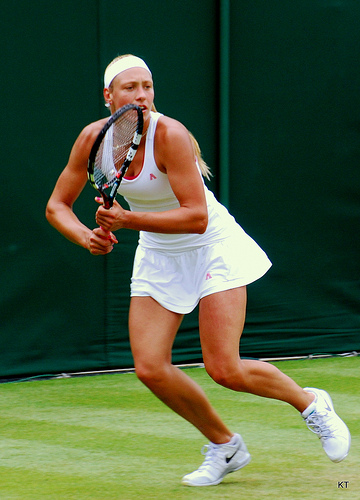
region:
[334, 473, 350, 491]
photo tag on the picture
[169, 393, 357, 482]
white tennis shoes with the nike swoosh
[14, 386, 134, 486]
green grass on the tennis court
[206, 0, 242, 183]
pole at the back of the court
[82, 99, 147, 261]
tennis racket in the girl's hand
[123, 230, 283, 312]
white tennis skirt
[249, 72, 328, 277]
green tarp wall behind the court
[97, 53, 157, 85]
white sweat band on the girl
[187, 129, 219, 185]
blonde hair down her back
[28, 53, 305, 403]
girl playing tennis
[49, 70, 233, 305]
woman holding a tennis racket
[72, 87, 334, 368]
woman wearing a tennis uniform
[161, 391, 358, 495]
woman wearing tennis shoes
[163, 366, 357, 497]
woman wearing nike sneakers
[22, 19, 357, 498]
woman standing on tennis court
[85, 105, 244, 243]
woman wearing a white tank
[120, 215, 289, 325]
woman wearing a white skirt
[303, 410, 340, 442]
shoelaces on white shoe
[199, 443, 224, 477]
shoelaces on white shoe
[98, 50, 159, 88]
woman wearing a headband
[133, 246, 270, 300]
short white tennis skirt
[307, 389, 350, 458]
white tennis shoes with dark check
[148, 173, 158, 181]
hot pink symbol on shirt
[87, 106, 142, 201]
black and white tennis racket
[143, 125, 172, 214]
white tank top with emblem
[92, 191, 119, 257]
hands holding tennis racket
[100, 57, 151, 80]
solid white head band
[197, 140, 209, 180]
strands of long blonde hair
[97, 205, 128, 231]
hand gripping handle of racket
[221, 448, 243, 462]
dark emblem on white shoe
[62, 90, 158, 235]
a black tennis racket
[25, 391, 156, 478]
a green tennis court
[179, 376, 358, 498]
white and black nike sneakers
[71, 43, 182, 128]
a woman wearing a white headband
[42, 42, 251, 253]
a woman playing tennis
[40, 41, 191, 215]
a woman holding a tennis racket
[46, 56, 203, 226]
a woman wearing a tank top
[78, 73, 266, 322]
a woman wearing a white skirt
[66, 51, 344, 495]
a woman wearing nike sneakers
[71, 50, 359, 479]
a woman wearing white nike sneakers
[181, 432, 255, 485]
Foot of tennis player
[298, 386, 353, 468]
Foot of tennis player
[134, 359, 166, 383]
Knee of tennis player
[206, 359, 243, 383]
Knee of tennis player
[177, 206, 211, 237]
Elbow of tennis player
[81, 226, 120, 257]
Hand of tennis player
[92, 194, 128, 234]
Hand of tennis player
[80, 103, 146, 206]
Racket belonging to tennis player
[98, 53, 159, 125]
Head of tennis player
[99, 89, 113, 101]
Ear of tennis player